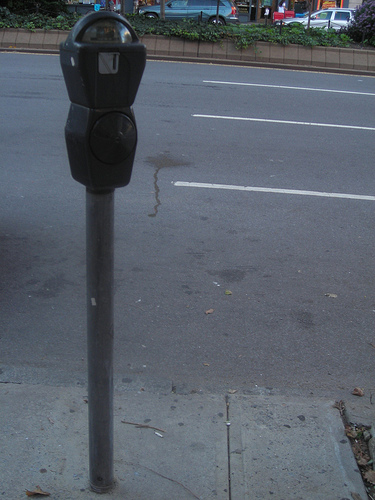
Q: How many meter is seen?
A: 1.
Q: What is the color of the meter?
A: Black.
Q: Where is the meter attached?
A: To the pole.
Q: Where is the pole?
A: In the sidewalk.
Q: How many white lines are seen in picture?
A: 3.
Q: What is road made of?
A: Tarmacked.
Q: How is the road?
A: Dirty.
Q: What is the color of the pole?
A: Grey.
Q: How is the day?
A: Sunny.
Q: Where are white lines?
A: On the road.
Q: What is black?
A: A parking meter.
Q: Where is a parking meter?
A: On the sidewalk.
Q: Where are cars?
A: On the street.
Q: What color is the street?
A: Grey.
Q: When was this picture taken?
A: Daytime.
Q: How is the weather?
A: Overcast.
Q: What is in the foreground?
A: A parking meter.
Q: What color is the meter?
A: Black.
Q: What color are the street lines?
A: White.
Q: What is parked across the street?
A: Cars.